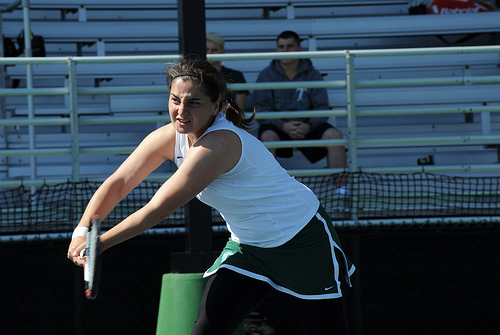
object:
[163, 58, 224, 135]
head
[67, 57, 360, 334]
tennis player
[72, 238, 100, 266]
hands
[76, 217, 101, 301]
racket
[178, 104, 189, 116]
nose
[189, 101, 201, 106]
eyes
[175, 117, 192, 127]
mouth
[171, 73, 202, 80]
headband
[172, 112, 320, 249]
tanktop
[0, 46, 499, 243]
fence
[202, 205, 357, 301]
skirt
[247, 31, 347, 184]
men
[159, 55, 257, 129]
hair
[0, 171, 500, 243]
mesh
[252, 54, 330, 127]
hoodie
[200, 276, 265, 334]
leggings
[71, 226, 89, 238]
wristband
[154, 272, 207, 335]
base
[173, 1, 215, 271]
pole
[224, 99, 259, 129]
ponytail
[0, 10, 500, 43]
bleachers